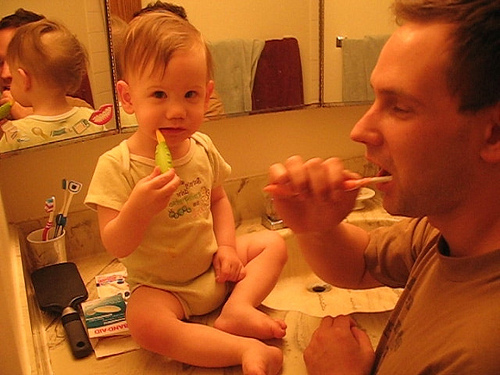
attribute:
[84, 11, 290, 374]
baby — brushing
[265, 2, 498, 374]
man — brushing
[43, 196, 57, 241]
toothbrush — green, orange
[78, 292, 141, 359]
box — bandages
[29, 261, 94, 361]
brush — black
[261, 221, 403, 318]
sink — bathroom, basin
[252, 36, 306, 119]
towel — hanging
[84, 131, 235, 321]
onesie — white